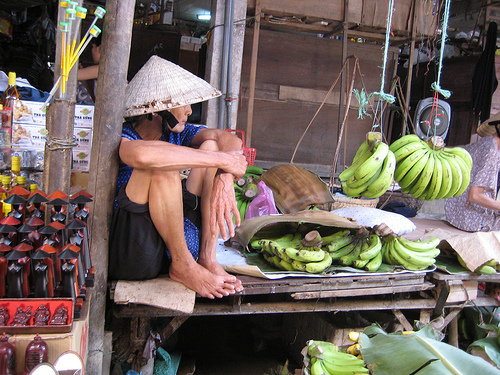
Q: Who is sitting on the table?
A: A woman.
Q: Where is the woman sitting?
A: On a table.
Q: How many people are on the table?
A: One.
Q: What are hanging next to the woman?
A: Bananas.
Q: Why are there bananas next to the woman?
A: To sell.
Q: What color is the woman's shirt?
A: Blue.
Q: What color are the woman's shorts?
A: Black.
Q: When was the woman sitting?
A: Daytime.